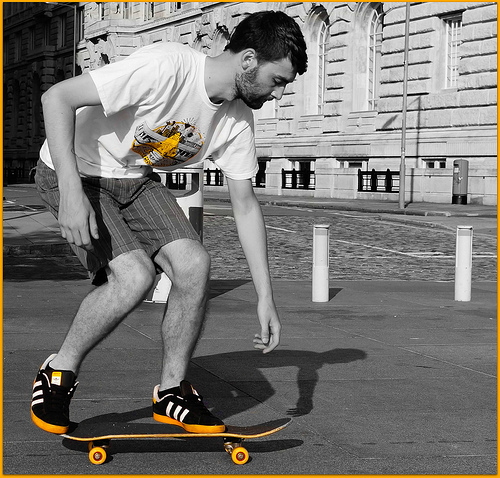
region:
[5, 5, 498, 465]
Black and white photo with orange enhanced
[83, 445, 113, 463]
Orange wheel on a skateboard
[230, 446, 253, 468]
Orange wheel on a skateboard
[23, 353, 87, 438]
Shoe with edited orange trim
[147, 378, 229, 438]
Shoe with edited orange trim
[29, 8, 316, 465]
Man about to do a trick on a skateboard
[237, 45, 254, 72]
Ear of a man on a skateboard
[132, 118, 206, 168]
Logo on a white shirt of a skateboarder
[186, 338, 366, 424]
Shadow of a man on a skateboard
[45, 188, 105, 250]
Hand of a man on a skateboard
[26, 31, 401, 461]
Man on a skateboard.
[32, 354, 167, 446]
Shoes on the skateboard.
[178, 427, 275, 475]
Wheel on the skateboard.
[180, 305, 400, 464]
Shadow on the ground.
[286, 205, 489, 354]
Grass in the background.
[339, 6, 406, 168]
Windows on the building.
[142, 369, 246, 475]
White stripes on the shoes.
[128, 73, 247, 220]
Yellow logo on the shirt.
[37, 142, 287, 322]
Striped shorts on the skater.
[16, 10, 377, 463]
A man is skateboarding on the sidewalk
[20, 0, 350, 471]
A man is outside during the daytime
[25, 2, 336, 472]
A man is getting some exercise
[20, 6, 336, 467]
A man is enjoying his day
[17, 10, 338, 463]
A man is using his skateboard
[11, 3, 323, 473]
A man's feet are on a skateboard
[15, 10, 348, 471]
A man is enjoying some recreation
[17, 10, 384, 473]
A man is casting a shadow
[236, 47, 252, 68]
The ear of the man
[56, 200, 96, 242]
The hand of a man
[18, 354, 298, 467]
orange accent on sneakers and skate board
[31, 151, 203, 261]
stripes on man's shorts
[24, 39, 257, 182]
T-shirt with orange accent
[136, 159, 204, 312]
Trash recepticle behind skateboarder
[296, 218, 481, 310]
posts to prevent through traffic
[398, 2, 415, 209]
a light pole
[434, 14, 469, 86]
rectangular small paned window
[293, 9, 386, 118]
arched windows on building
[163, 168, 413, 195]
wrought iron railings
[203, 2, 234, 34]
a keystone over building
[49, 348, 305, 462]
Man on a surfboard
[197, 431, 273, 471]
surfboard with yellow wheels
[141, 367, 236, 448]
Guy with black and yellow sneakers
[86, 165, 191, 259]
guy wearing plaid shorts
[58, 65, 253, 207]
guy with white tee shirt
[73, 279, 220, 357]
guy with hairy legs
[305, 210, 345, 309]
Pillars in the street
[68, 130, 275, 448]
Guy riding on a skateboard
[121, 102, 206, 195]
yellow and gray logo on a tee shirt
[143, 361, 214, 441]
black sneakers with white strips